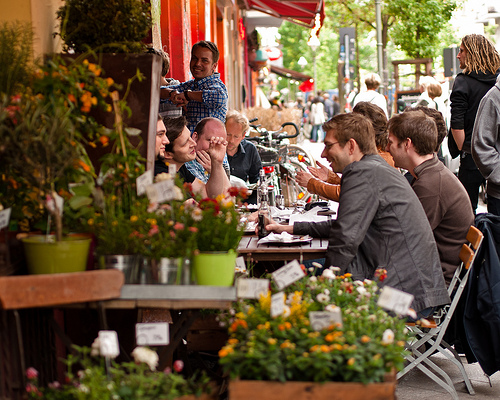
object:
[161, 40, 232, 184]
man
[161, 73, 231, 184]
shirt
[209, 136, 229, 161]
hand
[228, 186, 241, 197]
flower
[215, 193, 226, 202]
flower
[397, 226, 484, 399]
chair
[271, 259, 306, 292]
card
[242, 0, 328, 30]
awning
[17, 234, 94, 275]
flower pot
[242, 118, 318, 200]
bicycle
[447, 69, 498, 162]
shirt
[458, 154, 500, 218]
pants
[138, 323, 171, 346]
sign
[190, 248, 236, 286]
flower pot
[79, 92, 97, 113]
flower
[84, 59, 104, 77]
flower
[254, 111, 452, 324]
man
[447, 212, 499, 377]
jacket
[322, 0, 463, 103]
tree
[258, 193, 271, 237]
bottle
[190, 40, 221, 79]
head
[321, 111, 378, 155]
hair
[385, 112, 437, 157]
hair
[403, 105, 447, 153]
hair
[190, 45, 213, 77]
face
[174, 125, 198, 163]
face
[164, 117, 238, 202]
man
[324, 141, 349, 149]
eye glasses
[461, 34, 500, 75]
hair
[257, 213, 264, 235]
label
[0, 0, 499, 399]
scene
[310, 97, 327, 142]
person